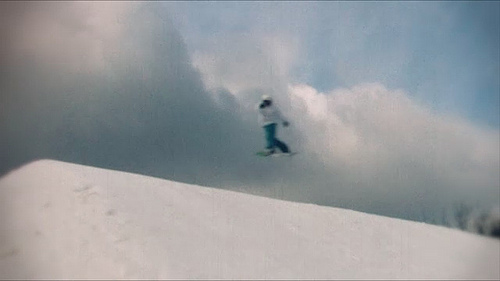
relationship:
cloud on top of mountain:
[0, 2, 499, 234] [1, 157, 499, 280]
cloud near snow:
[0, 2, 499, 234] [82, 167, 142, 205]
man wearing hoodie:
[256, 92, 292, 153] [257, 94, 287, 126]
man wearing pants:
[256, 92, 292, 153] [264, 122, 290, 151]